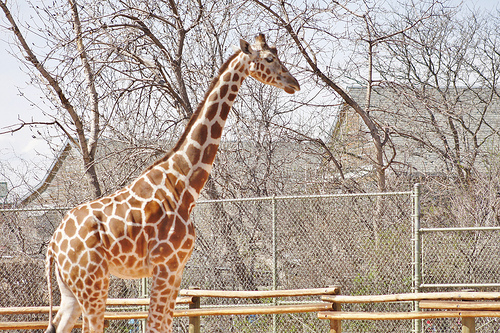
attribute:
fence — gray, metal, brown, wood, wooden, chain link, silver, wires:
[1, 183, 499, 331]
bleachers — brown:
[0, 278, 499, 331]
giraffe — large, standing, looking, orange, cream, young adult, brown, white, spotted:
[32, 22, 308, 332]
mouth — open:
[287, 81, 302, 94]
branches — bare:
[370, 6, 438, 51]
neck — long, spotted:
[175, 69, 252, 195]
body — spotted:
[41, 172, 198, 282]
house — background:
[310, 74, 500, 235]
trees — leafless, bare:
[253, 8, 414, 299]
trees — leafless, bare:
[351, 0, 499, 235]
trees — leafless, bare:
[0, 1, 130, 283]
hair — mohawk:
[145, 41, 240, 171]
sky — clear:
[1, 0, 499, 225]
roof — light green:
[345, 78, 499, 178]